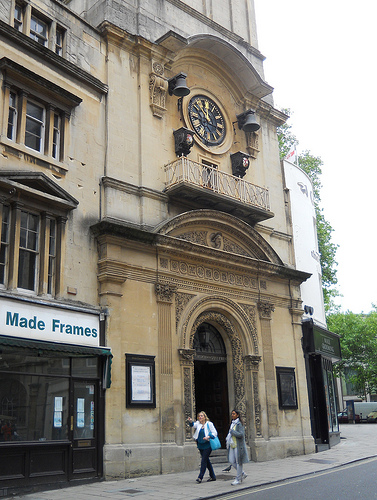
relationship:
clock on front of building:
[178, 84, 234, 155] [0, 0, 315, 499]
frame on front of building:
[125, 352, 157, 408] [0, 0, 315, 499]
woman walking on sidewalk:
[188, 410, 222, 483] [20, 419, 376, 498]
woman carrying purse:
[188, 410, 222, 483] [205, 422, 220, 450]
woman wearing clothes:
[226, 407, 247, 484] [227, 421, 249, 466]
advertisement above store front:
[0, 290, 106, 348] [0, 290, 113, 499]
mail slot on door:
[75, 438, 92, 447] [69, 374, 103, 485]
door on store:
[69, 374, 103, 485] [0, 289, 113, 498]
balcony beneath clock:
[162, 155, 275, 222] [178, 84, 234, 155]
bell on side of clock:
[238, 104, 262, 132] [181, 93, 233, 146]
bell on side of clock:
[168, 72, 190, 97] [181, 93, 233, 146]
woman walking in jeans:
[183, 410, 228, 486] [198, 444, 218, 479]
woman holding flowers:
[183, 410, 228, 486] [185, 418, 194, 431]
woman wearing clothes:
[226, 409, 250, 486] [225, 425, 249, 474]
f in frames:
[48, 311, 60, 331] [47, 316, 103, 337]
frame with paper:
[124, 349, 156, 409] [128, 363, 149, 401]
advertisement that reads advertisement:
[0, 296, 100, 347] [0, 296, 100, 347]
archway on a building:
[163, 289, 267, 353] [103, 3, 323, 484]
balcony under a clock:
[165, 160, 274, 224] [177, 89, 242, 154]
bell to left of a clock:
[170, 72, 191, 96] [180, 89, 229, 146]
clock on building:
[188, 94, 226, 146] [103, 3, 323, 484]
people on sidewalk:
[183, 404, 250, 483] [20, 419, 376, 498]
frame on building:
[125, 352, 157, 408] [89, 4, 328, 497]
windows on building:
[0, 199, 71, 301] [0, 0, 119, 485]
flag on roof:
[279, 134, 299, 164] [276, 136, 321, 201]